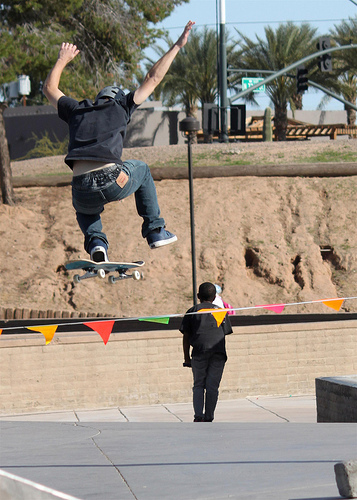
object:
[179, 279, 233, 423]
boy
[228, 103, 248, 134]
light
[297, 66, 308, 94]
light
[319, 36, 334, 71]
light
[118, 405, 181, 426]
square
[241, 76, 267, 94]
traffic sign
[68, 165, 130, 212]
blue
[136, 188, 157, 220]
blue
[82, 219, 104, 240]
blue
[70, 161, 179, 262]
jeans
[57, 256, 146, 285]
skateboard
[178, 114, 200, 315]
light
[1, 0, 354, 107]
sky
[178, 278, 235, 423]
kid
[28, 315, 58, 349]
flag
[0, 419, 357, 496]
concrete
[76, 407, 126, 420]
square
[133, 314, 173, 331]
flag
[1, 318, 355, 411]
brick wall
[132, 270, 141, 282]
white wheels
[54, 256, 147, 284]
board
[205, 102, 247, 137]
street light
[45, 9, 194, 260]
boy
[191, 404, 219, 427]
pad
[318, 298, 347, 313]
orange flag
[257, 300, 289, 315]
flag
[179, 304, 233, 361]
black shirt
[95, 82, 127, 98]
helmet